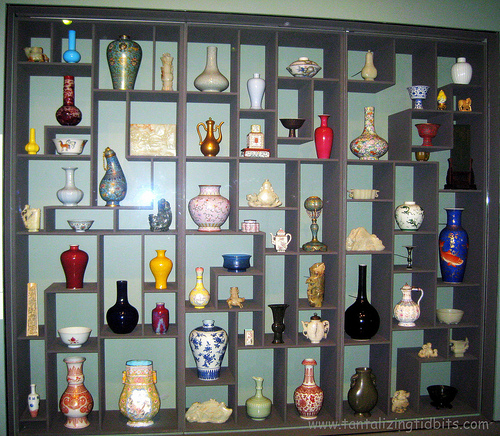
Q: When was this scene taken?
A: Yesterday.